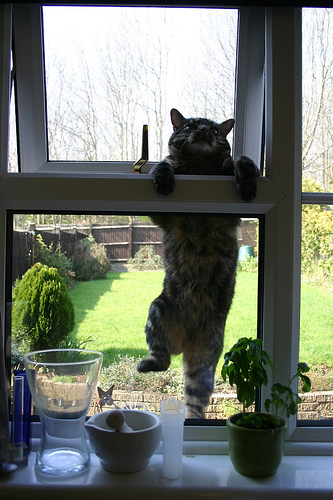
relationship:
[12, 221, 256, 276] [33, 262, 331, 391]
fence in back yard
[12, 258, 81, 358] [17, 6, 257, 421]
bush outside of window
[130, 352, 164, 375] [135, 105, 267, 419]
right foot of cat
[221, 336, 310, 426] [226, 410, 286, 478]
plant in container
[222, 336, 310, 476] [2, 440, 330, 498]
potted plant on windowsil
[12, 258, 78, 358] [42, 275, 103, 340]
bush in shade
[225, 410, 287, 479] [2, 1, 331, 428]
pot on window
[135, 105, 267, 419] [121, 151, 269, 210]
cat has legs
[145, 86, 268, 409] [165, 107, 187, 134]
cat has ear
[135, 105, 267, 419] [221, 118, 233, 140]
cat has ear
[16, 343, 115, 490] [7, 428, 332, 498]
vase in windowsil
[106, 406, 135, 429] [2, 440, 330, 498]
pestle on windowsil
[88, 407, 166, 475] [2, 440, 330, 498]
mortar on windowsil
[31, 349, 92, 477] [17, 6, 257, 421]
hourglass on window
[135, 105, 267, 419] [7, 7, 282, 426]
cat climbing in window